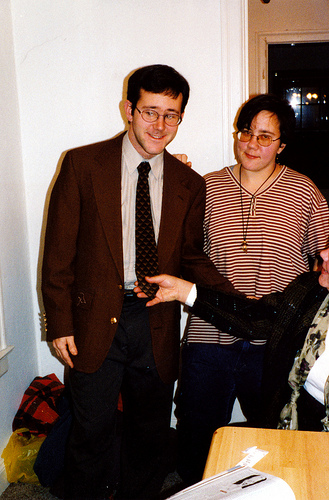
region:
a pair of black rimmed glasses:
[131, 104, 181, 125]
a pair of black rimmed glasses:
[235, 129, 281, 146]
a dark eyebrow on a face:
[141, 103, 158, 110]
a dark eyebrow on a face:
[165, 107, 179, 113]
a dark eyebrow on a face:
[244, 125, 252, 130]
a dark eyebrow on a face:
[258, 128, 276, 135]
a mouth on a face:
[145, 130, 168, 138]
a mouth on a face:
[243, 149, 261, 158]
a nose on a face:
[155, 113, 165, 130]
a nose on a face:
[247, 133, 259, 149]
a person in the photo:
[35, 57, 207, 496]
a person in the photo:
[172, 78, 324, 477]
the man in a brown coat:
[34, 128, 199, 492]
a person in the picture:
[136, 242, 325, 436]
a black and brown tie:
[126, 161, 164, 296]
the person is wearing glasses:
[130, 98, 189, 132]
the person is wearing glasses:
[231, 129, 283, 149]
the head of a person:
[118, 62, 190, 152]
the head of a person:
[226, 90, 305, 171]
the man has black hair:
[112, 63, 193, 154]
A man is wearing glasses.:
[119, 85, 185, 154]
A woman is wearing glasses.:
[223, 92, 291, 180]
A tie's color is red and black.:
[97, 142, 172, 309]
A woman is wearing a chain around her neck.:
[217, 152, 285, 262]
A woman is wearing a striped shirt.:
[172, 147, 328, 366]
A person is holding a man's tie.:
[104, 225, 328, 443]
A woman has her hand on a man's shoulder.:
[146, 94, 291, 183]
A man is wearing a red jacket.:
[31, 124, 270, 382]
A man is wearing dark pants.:
[23, 269, 189, 498]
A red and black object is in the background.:
[2, 362, 74, 449]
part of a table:
[269, 439, 297, 474]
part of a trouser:
[90, 425, 129, 469]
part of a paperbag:
[13, 447, 35, 470]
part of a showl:
[26, 375, 51, 415]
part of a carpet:
[20, 484, 38, 491]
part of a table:
[291, 460, 305, 485]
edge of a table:
[204, 440, 214, 454]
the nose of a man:
[152, 111, 167, 133]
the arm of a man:
[29, 146, 87, 327]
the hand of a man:
[49, 321, 82, 371]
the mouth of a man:
[144, 130, 170, 142]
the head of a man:
[121, 60, 189, 158]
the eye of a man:
[142, 108, 157, 117]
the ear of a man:
[123, 96, 133, 125]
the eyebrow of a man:
[139, 101, 162, 113]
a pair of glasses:
[128, 100, 185, 128]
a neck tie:
[133, 159, 167, 300]